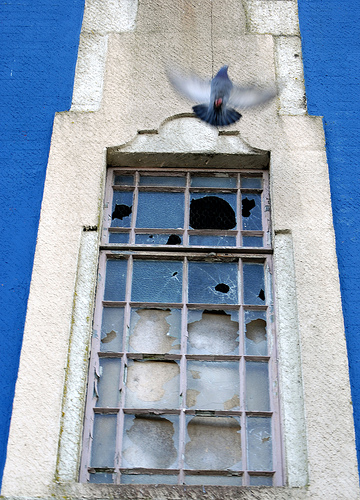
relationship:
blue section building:
[6, 176, 48, 216] [0, 6, 348, 205]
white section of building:
[78, 31, 298, 80] [0, 6, 348, 205]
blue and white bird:
[6, 176, 48, 216] [159, 54, 272, 129]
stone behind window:
[133, 312, 167, 345] [90, 174, 260, 315]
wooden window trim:
[103, 172, 165, 209] [222, 189, 258, 206]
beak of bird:
[223, 61, 246, 75] [149, 61, 246, 150]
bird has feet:
[149, 61, 246, 150] [209, 89, 229, 107]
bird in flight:
[149, 61, 246, 150] [193, 56, 273, 90]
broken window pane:
[181, 185, 236, 233] [166, 184, 248, 244]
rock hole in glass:
[209, 276, 236, 295] [171, 257, 264, 317]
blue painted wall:
[6, 176, 48, 216] [312, 22, 345, 54]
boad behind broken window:
[104, 320, 259, 418] [95, 251, 262, 413]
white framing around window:
[73, 248, 145, 286] [90, 174, 260, 315]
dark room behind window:
[196, 203, 221, 222] [90, 174, 260, 315]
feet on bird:
[209, 89, 229, 107] [149, 61, 246, 150]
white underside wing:
[186, 86, 205, 97] [153, 62, 214, 110]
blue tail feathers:
[6, 176, 48, 216] [218, 105, 241, 138]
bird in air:
[149, 61, 246, 150] [244, 63, 271, 86]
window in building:
[90, 174, 260, 315] [0, 6, 348, 205]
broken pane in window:
[181, 185, 236, 233] [90, 174, 260, 315]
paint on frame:
[262, 184, 273, 237] [174, 167, 246, 202]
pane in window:
[166, 184, 248, 244] [90, 174, 260, 315]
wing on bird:
[153, 62, 214, 110] [149, 61, 246, 150]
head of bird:
[211, 54, 232, 79] [149, 61, 246, 150]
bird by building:
[149, 61, 246, 150] [0, 6, 348, 205]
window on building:
[90, 174, 260, 315] [0, 6, 348, 205]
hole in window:
[200, 200, 227, 224] [90, 174, 260, 315]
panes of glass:
[124, 170, 240, 246] [148, 170, 280, 297]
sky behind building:
[316, 34, 329, 56] [0, 6, 348, 205]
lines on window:
[12, 45, 85, 85] [90, 174, 260, 315]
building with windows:
[0, 6, 348, 205] [69, 150, 273, 437]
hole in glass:
[200, 200, 227, 224] [148, 170, 280, 297]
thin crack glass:
[145, 275, 170, 299] [148, 170, 280, 297]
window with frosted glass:
[90, 174, 260, 315] [130, 198, 157, 235]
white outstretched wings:
[186, 86, 205, 97] [132, 63, 286, 103]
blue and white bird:
[6, 176, 48, 216] [149, 61, 246, 150]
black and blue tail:
[157, 106, 244, 142] [191, 109, 238, 130]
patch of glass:
[159, 198, 188, 222] [148, 170, 280, 297]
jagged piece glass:
[187, 309, 210, 335] [148, 170, 280, 297]